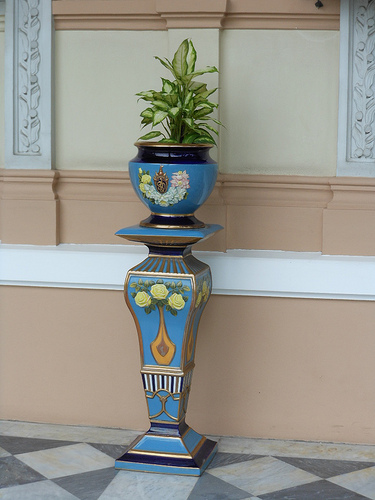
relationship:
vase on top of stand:
[108, 34, 241, 249] [97, 225, 246, 479]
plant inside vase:
[131, 36, 226, 137] [108, 34, 241, 249]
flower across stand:
[131, 279, 187, 361] [97, 225, 246, 479]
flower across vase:
[136, 164, 191, 206] [108, 34, 241, 249]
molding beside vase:
[243, 168, 259, 175] [108, 34, 241, 249]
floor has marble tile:
[233, 447, 371, 494] [224, 445, 326, 490]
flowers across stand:
[131, 279, 187, 361] [97, 225, 246, 479]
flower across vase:
[131, 279, 187, 361] [108, 34, 241, 249]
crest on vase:
[136, 142, 214, 149] [108, 34, 241, 249]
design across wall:
[11, 2, 45, 163] [68, 45, 113, 66]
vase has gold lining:
[108, 34, 241, 249] [136, 142, 214, 149]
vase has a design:
[108, 34, 241, 249] [136, 164, 191, 206]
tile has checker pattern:
[224, 445, 326, 490] [233, 447, 371, 494]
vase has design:
[108, 34, 241, 249] [136, 164, 191, 206]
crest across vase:
[136, 142, 214, 149] [108, 34, 241, 249]